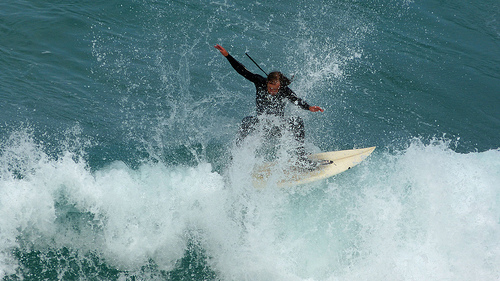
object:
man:
[213, 39, 332, 173]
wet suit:
[206, 53, 310, 147]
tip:
[339, 132, 383, 176]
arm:
[224, 53, 260, 84]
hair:
[268, 71, 295, 88]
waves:
[0, 9, 500, 281]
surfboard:
[237, 145, 383, 185]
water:
[0, 0, 500, 281]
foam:
[4, 130, 494, 279]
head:
[263, 72, 290, 88]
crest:
[0, 129, 498, 264]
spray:
[4, 13, 497, 278]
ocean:
[0, 0, 492, 281]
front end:
[285, 142, 375, 186]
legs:
[275, 115, 317, 169]